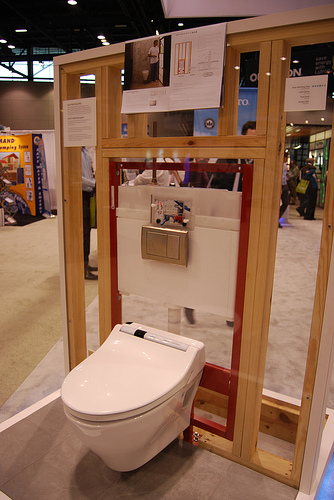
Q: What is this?
A: Toilet.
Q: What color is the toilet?
A: White.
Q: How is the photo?
A: Clear.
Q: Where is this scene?
A: At a convention.